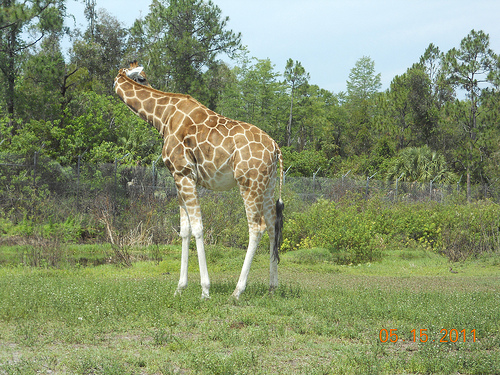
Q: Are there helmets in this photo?
A: No, there are no helmets.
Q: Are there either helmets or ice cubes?
A: No, there are no helmets or ice cubes.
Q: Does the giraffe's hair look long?
A: Yes, the hair is long.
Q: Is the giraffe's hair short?
A: No, the hair is long.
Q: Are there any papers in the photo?
A: No, there are no papers.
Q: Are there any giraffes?
A: Yes, there is a giraffe.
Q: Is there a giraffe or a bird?
A: Yes, there is a giraffe.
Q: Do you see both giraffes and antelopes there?
A: No, there is a giraffe but no antelopes.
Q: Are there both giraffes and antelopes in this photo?
A: No, there is a giraffe but no antelopes.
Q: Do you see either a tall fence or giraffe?
A: Yes, there is a tall giraffe.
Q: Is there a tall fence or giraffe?
A: Yes, there is a tall giraffe.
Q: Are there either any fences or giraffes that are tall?
A: Yes, the giraffe is tall.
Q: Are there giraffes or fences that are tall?
A: Yes, the giraffe is tall.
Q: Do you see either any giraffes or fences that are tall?
A: Yes, the giraffe is tall.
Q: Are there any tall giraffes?
A: Yes, there is a tall giraffe.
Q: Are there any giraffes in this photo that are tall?
A: Yes, there is a giraffe that is tall.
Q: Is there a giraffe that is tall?
A: Yes, there is a giraffe that is tall.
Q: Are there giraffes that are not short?
A: Yes, there is a tall giraffe.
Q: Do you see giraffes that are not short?
A: Yes, there is a tall giraffe.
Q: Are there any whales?
A: No, there are no whales.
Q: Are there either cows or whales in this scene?
A: No, there are no whales or cows.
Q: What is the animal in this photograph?
A: The animal is a giraffe.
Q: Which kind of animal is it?
A: The animal is a giraffe.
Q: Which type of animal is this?
A: This is a giraffe.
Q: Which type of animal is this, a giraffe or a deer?
A: This is a giraffe.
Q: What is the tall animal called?
A: The animal is a giraffe.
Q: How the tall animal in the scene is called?
A: The animal is a giraffe.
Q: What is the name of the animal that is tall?
A: The animal is a giraffe.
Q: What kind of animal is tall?
A: The animal is a giraffe.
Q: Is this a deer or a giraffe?
A: This is a giraffe.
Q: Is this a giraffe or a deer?
A: This is a giraffe.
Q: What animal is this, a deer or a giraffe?
A: This is a giraffe.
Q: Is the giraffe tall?
A: Yes, the giraffe is tall.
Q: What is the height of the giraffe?
A: The giraffe is tall.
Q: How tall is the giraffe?
A: The giraffe is tall.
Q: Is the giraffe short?
A: No, the giraffe is tall.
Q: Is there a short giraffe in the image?
A: No, there is a giraffe but it is tall.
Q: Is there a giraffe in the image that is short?
A: No, there is a giraffe but it is tall.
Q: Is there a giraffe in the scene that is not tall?
A: No, there is a giraffe but it is tall.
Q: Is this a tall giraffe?
A: Yes, this is a tall giraffe.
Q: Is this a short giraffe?
A: No, this is a tall giraffe.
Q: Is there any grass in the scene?
A: Yes, there is grass.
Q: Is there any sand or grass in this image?
A: Yes, there is grass.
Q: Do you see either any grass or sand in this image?
A: Yes, there is grass.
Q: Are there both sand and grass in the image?
A: No, there is grass but no sand.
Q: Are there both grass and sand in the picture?
A: No, there is grass but no sand.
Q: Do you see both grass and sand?
A: No, there is grass but no sand.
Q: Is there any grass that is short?
A: Yes, there is short grass.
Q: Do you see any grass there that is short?
A: Yes, there is grass that is short.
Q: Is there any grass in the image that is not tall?
A: Yes, there is short grass.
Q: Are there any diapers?
A: No, there are no diapers.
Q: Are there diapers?
A: No, there are no diapers.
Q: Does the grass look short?
A: Yes, the grass is short.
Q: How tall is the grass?
A: The grass is short.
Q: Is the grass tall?
A: No, the grass is short.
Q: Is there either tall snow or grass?
A: No, there is grass but it is short.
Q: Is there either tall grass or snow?
A: No, there is grass but it is short.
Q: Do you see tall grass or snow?
A: No, there is grass but it is short.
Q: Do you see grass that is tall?
A: No, there is grass but it is short.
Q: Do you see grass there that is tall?
A: No, there is grass but it is short.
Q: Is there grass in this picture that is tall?
A: No, there is grass but it is short.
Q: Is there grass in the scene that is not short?
A: No, there is grass but it is short.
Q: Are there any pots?
A: No, there are no pots.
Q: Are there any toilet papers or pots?
A: No, there are no pots or toilet papers.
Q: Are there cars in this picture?
A: No, there are no cars.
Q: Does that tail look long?
A: Yes, the tail is long.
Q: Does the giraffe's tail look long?
A: Yes, the tail is long.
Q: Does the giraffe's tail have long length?
A: Yes, the tail is long.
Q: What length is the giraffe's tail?
A: The tail is long.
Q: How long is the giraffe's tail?
A: The tail is long.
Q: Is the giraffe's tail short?
A: No, the tail is long.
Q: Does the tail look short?
A: No, the tail is long.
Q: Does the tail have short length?
A: No, the tail is long.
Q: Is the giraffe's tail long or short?
A: The tail is long.